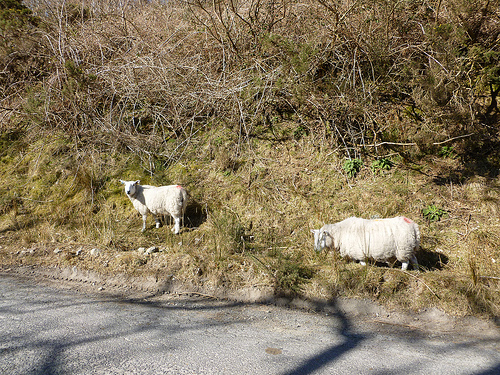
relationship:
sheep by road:
[124, 167, 430, 290] [53, 290, 322, 373]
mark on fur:
[401, 214, 415, 226] [339, 226, 407, 258]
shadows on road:
[53, 287, 158, 337] [53, 290, 322, 373]